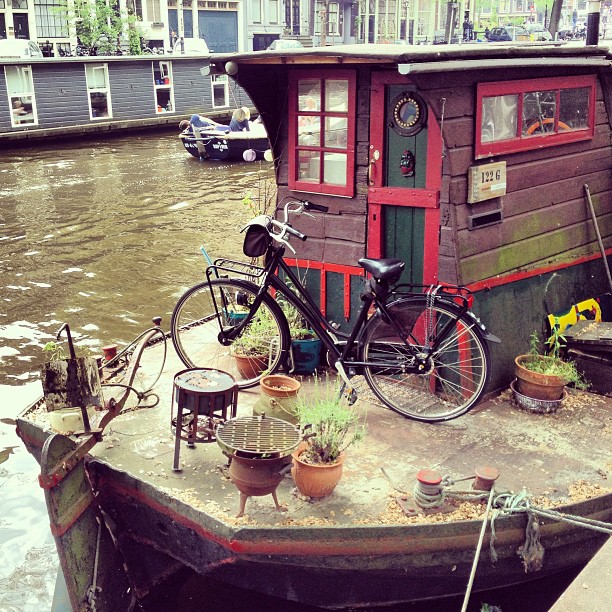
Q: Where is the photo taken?
A: At a boat dock.